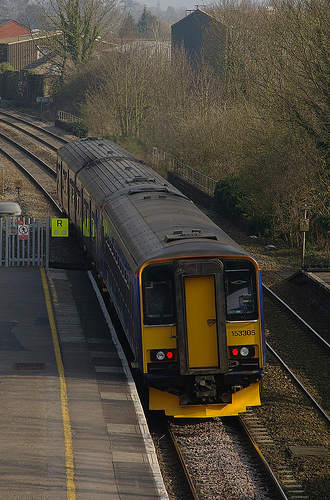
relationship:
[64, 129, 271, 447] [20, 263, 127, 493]
train at platform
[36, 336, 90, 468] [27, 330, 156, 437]
line on ground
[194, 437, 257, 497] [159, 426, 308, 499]
rocks on traintracks